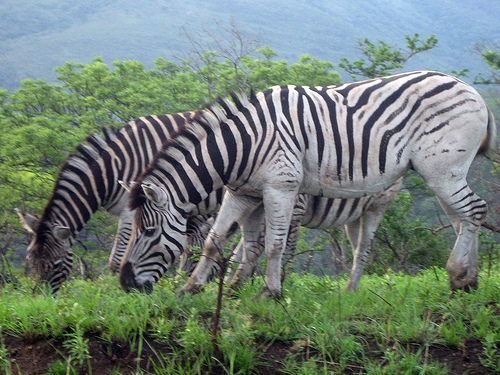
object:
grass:
[248, 295, 312, 339]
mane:
[128, 90, 245, 213]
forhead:
[116, 180, 188, 295]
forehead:
[136, 206, 150, 231]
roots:
[57, 278, 157, 361]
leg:
[419, 172, 488, 266]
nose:
[119, 277, 133, 293]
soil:
[1, 349, 86, 370]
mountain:
[2, 2, 499, 81]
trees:
[0, 17, 500, 217]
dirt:
[7, 332, 80, 375]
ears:
[118, 180, 139, 193]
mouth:
[139, 282, 152, 295]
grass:
[7, 280, 60, 339]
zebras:
[24, 63, 474, 307]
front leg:
[172, 188, 261, 296]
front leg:
[251, 152, 303, 304]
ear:
[14, 207, 40, 234]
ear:
[57, 228, 71, 239]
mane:
[35, 120, 108, 242]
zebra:
[11, 109, 244, 296]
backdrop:
[0, 0, 499, 260]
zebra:
[116, 69, 495, 302]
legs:
[262, 189, 297, 288]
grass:
[393, 277, 491, 347]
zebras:
[109, 176, 406, 302]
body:
[218, 69, 440, 198]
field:
[3, 270, 496, 371]